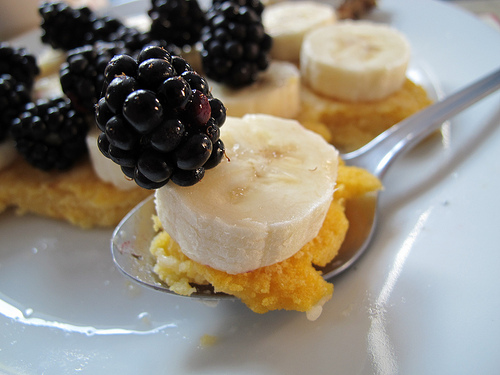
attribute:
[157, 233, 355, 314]
fritter — fruit topped, crispy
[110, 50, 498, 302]
spoon — full, sliver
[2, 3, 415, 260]
topping — fruit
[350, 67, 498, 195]
handle — sliver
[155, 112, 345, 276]
bananna — sliced, one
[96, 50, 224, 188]
blackberry — juicy, black, one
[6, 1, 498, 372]
dish — ceramic, white, plate, glass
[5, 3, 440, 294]
breakfast — delicious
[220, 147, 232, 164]
stem — small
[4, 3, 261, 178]
berries — stacked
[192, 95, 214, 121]
sement — less ripe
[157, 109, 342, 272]
slice — one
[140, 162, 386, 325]
crust — yellow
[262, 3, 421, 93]
slices — sliced, thick